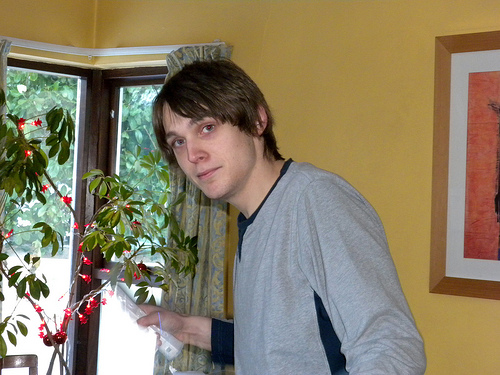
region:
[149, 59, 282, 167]
the man has brown hair.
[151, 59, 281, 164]
the man's hair is straight.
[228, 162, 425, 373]
the man is wearing gray and black shirt.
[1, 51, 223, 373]
two windows in background.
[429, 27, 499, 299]
picture on the wall.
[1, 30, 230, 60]
curtain rod on the wall.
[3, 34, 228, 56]
the curtain rod is white.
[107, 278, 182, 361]
white object in man's hand.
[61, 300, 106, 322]
red berries on plant.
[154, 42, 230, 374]
curtain in the background.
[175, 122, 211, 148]
The eyes of the man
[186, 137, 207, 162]
The nose of the man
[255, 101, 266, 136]
The left ear of the man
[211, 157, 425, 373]
The man is wearing a white and blue shirt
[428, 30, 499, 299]
A picture hanging on the wall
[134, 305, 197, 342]
The right hand of the man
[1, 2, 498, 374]
Walls behind the man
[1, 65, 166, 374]
A window near the man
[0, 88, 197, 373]
A plant near the window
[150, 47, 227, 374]
A curtain by the window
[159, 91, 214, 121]
hair laying on the forehead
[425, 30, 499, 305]
artwork on the wall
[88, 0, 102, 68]
corner of the wall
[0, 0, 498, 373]
yellow paint on the walls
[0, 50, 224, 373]
large windows on the wall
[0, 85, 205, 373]
small plant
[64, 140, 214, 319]
green leaves on the tree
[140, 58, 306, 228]
head is turned to the side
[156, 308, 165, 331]
thin white stripe around the thumb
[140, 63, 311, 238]
head is bent down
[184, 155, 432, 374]
gray and blue shirt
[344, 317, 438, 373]
wrinkles on the sleeve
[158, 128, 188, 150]
eyebrow above the eye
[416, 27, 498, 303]
artwork hanging on the wall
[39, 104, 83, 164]
green leaves on the branch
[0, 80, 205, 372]
thin plant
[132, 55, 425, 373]
A young man in a grey and black shirt.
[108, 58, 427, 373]
The young man is holding a game controller.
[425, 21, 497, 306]
A painting in a wooden frame.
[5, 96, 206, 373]
A green plant with red flowers.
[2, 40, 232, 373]
Paisley curtains surround a window.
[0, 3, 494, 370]
The walls are golden yellow.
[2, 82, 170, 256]
Tree branches outside of a window.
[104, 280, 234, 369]
A hand holding a game controller.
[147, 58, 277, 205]
A young man with brown hair.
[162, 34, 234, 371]
A panel of paisley curtains.